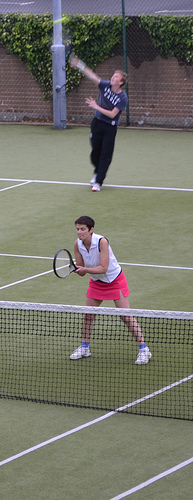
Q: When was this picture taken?
A: During the daytime.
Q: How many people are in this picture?
A: Two.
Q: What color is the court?
A: Green.